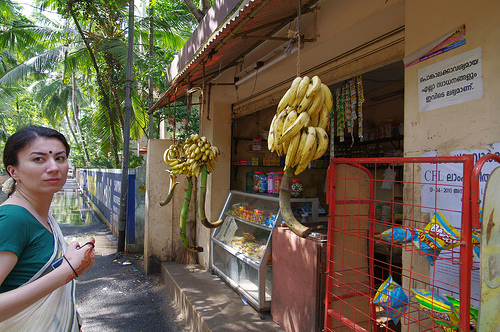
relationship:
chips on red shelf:
[413, 210, 462, 264] [321, 151, 498, 329]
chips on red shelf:
[367, 273, 410, 325] [321, 151, 498, 329]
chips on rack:
[365, 219, 417, 251] [332, 209, 487, 279]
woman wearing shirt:
[6, 116, 100, 327] [8, 206, 100, 313]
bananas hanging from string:
[259, 73, 351, 177] [279, 41, 321, 80]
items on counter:
[247, 165, 318, 193] [182, 191, 322, 310]